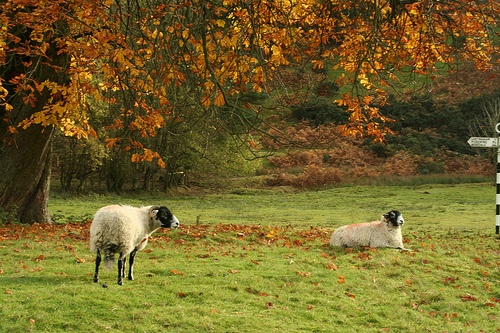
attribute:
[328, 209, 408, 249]
sheep — white, black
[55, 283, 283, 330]
grass — green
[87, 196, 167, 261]
wool — white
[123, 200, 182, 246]
head — black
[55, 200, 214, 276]
sheep — standing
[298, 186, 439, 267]
sheep — seated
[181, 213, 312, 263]
leaves — dry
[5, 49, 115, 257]
tree — tall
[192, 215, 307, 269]
leaves — red, yellow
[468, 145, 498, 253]
signpost — white, black, patterned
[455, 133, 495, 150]
sign — pointing left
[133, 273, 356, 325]
grass — green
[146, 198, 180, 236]
head — black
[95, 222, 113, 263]
tail — white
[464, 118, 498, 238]
signpost — black, white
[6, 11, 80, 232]
tree trunk — thick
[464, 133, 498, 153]
arrow — white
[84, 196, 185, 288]
ram — white, black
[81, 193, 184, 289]
sheep — white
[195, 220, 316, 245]
leaves — brown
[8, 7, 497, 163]
leaves — red, yellow